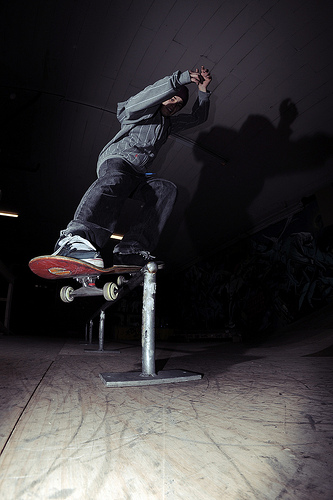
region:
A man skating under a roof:
[90, 69, 180, 292]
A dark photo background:
[262, 283, 329, 359]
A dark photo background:
[255, 158, 313, 229]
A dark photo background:
[0, 212, 38, 292]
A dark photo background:
[200, 122, 296, 207]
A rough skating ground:
[214, 409, 330, 477]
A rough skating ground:
[206, 334, 329, 401]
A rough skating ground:
[9, 420, 155, 488]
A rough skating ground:
[7, 332, 88, 409]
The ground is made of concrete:
[53, 406, 286, 487]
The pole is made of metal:
[135, 272, 174, 376]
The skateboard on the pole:
[24, 248, 147, 316]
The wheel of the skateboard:
[54, 277, 122, 305]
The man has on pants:
[63, 156, 180, 254]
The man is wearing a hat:
[169, 82, 191, 108]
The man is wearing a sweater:
[93, 73, 214, 177]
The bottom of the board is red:
[26, 251, 143, 284]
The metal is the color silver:
[140, 258, 160, 377]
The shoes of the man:
[46, 220, 171, 278]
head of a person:
[150, 72, 193, 126]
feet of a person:
[48, 233, 104, 270]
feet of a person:
[108, 244, 169, 268]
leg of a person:
[71, 175, 115, 253]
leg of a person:
[135, 198, 176, 245]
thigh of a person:
[94, 156, 134, 201]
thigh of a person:
[137, 169, 173, 199]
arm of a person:
[120, 68, 169, 105]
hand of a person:
[180, 62, 206, 91]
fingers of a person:
[199, 64, 216, 76]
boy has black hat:
[158, 67, 183, 106]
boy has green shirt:
[105, 90, 187, 163]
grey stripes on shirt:
[105, 91, 185, 161]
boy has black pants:
[95, 155, 175, 243]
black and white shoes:
[23, 232, 109, 270]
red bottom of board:
[18, 258, 145, 279]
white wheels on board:
[56, 281, 120, 304]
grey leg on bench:
[125, 254, 180, 381]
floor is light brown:
[141, 402, 279, 496]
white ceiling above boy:
[204, 2, 276, 125]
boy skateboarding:
[50, 65, 208, 302]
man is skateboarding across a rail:
[26, 254, 230, 383]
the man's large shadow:
[185, 98, 328, 272]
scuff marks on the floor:
[0, 329, 324, 490]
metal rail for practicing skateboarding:
[75, 257, 200, 379]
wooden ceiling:
[3, 2, 306, 257]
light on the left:
[0, 202, 16, 221]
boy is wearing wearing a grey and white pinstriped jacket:
[101, 53, 210, 160]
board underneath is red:
[26, 258, 123, 294]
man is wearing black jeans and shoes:
[61, 156, 176, 269]